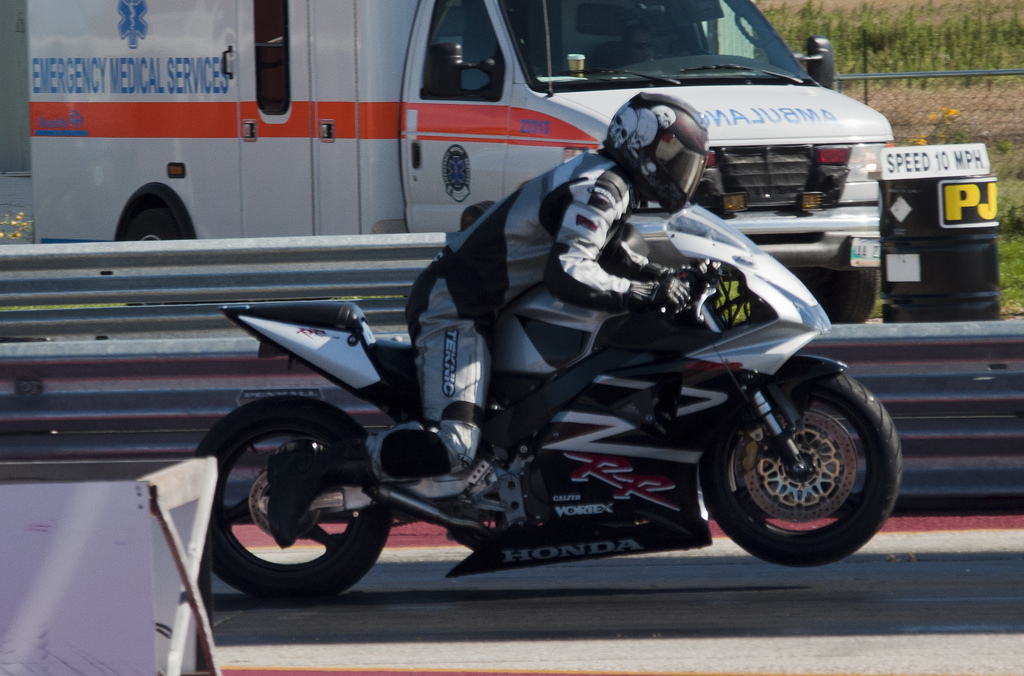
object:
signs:
[881, 142, 993, 180]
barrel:
[866, 170, 998, 322]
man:
[263, 90, 710, 546]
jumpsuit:
[365, 153, 650, 480]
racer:
[268, 90, 708, 546]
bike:
[195, 201, 899, 603]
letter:
[945, 184, 980, 221]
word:
[503, 537, 642, 562]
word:
[555, 502, 615, 517]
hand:
[630, 277, 691, 314]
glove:
[629, 276, 692, 318]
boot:
[268, 438, 377, 548]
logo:
[443, 329, 459, 396]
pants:
[365, 269, 488, 481]